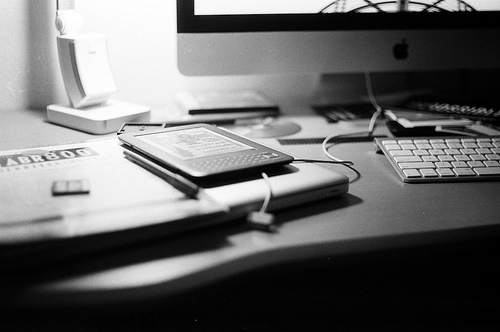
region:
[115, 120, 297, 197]
black powered on PDA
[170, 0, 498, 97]
apple black and white computer monitor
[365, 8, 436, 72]
Apple Company symbol on computer monitor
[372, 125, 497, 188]
light colored computer keyboard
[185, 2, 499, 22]
powered on screen of computer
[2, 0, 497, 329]
desk with several electronic on it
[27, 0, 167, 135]
white colored lamp base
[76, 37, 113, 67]
power button on white lamp base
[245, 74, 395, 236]
welectronic and electric cords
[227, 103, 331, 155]
silver CD laying on desk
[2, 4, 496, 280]
gadgets on desk top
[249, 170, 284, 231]
white charger on computer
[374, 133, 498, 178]
key board on desk top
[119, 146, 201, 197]
ink pen on magazine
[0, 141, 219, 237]
magazine sitting on a desk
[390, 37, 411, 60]
APPLE logo on computer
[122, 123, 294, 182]
kindle on top of desk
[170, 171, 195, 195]
pen cap on pen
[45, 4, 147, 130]
gadget on charger on desk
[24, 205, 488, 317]
edge of desk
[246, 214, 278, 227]
end of charger unused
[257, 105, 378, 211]
cord of charger goes to wall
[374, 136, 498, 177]
keyboard in frotn of computer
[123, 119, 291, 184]
ereader on top of charger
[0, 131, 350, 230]
lap top under charger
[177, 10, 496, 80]
monitor with apple sign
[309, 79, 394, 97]
stand of monitor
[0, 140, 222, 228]
material with writing on it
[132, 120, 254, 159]
screen of ereader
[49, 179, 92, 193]
memory chip by pen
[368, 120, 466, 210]
keyboard on the table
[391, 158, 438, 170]
number on the keyboard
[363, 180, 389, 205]
table under the keyboard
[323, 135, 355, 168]
wire next to the keyboard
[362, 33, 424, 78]
apple icon on the computer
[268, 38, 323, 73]
white part of the computer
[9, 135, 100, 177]
words on an object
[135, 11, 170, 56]
light behind the computer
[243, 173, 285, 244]
cord on the table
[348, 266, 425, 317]
black area under the table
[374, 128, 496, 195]
grey keyboard with white keys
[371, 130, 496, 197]
mac brand keyboard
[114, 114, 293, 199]
black tablet with stylus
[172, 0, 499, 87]
mac brand desktop screen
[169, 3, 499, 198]
apple mac desktop computer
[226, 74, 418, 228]
white apple charging cable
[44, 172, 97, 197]
square accessory on desk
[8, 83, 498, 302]
grey desk with multiple items on top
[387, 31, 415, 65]
apple logo on desktop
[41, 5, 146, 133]
white electronic on desk